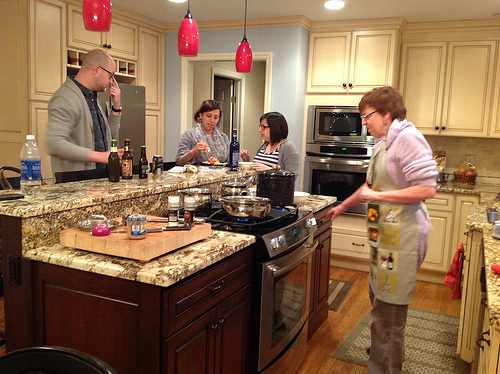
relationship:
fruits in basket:
[456, 167, 475, 175] [456, 172, 478, 185]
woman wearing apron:
[329, 87, 437, 373] [365, 141, 420, 308]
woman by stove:
[329, 87, 437, 373] [302, 156, 378, 218]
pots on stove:
[182, 170, 295, 224] [164, 197, 318, 373]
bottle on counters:
[19, 132, 41, 200] [2, 163, 338, 289]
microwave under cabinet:
[307, 104, 382, 158] [305, 25, 401, 95]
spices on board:
[164, 194, 199, 225] [57, 214, 214, 263]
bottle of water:
[19, 132, 41, 200] [22, 181, 42, 199]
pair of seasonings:
[166, 194, 197, 225] [165, 193, 198, 225]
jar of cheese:
[126, 213, 147, 240] [129, 226, 147, 240]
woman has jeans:
[329, 87, 437, 373] [368, 282, 410, 373]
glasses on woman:
[360, 108, 380, 122] [329, 87, 437, 373]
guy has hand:
[46, 47, 123, 182] [109, 76, 122, 114]